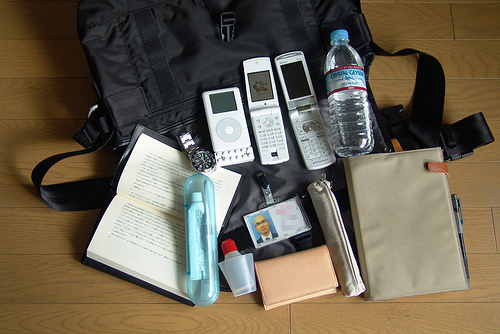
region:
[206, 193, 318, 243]
license on the floor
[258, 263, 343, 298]
wallet on the floor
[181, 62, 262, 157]
ipod on the floor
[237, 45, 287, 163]
phone on the floor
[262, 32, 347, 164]
phone on the floor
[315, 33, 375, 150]
water bottle on floor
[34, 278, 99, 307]
the floor is wood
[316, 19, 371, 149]
a bottle water laying on a bag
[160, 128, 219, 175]
a watch laying on a book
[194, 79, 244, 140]
an ipod laying on a bag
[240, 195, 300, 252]
an id badge laying on a bag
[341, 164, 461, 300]
an organizer laying on a bag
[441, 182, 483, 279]
a pen attached to an oraganizer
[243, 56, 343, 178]
two cellular phones laying on a bag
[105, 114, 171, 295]
a book is open on a bag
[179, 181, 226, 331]
a blue container laying on top of a book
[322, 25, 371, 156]
water bottle on backpack.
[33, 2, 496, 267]
black backpack on wood floor.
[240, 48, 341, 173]
two silver flip phones.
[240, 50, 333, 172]
the phones are silver.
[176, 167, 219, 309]
light blue toothbrush case.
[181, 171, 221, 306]
the case is light blue.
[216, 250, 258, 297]
clear plastic medicine cup.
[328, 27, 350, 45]
the bottle cap is blue.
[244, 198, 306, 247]
identification tag on backpack.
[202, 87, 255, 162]
silver mp3 player on backpack.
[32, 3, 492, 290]
A black shoulder bag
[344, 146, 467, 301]
A beige colored diary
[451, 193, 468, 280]
A pen clasped to the diary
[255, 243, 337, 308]
A peach colored wallet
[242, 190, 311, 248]
ID card of a man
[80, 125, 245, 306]
An open black covered book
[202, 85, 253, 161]
A white ipod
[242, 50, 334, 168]
Two white cell phones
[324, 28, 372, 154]
A plastic water bottle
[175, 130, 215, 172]
A black wristwatch with metal strap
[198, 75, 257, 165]
a white ipod on a bag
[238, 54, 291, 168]
a cellphone on a bag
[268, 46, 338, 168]
a cellphone on a bag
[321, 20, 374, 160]
a water bottle on a bag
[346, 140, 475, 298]
a book case on a bag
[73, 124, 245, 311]
a book on a bag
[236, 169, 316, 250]
a man's ID on a bag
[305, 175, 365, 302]
a long pouch on a bag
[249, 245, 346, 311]
a beige wallet on a bag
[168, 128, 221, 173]
a wrist watch on a bag